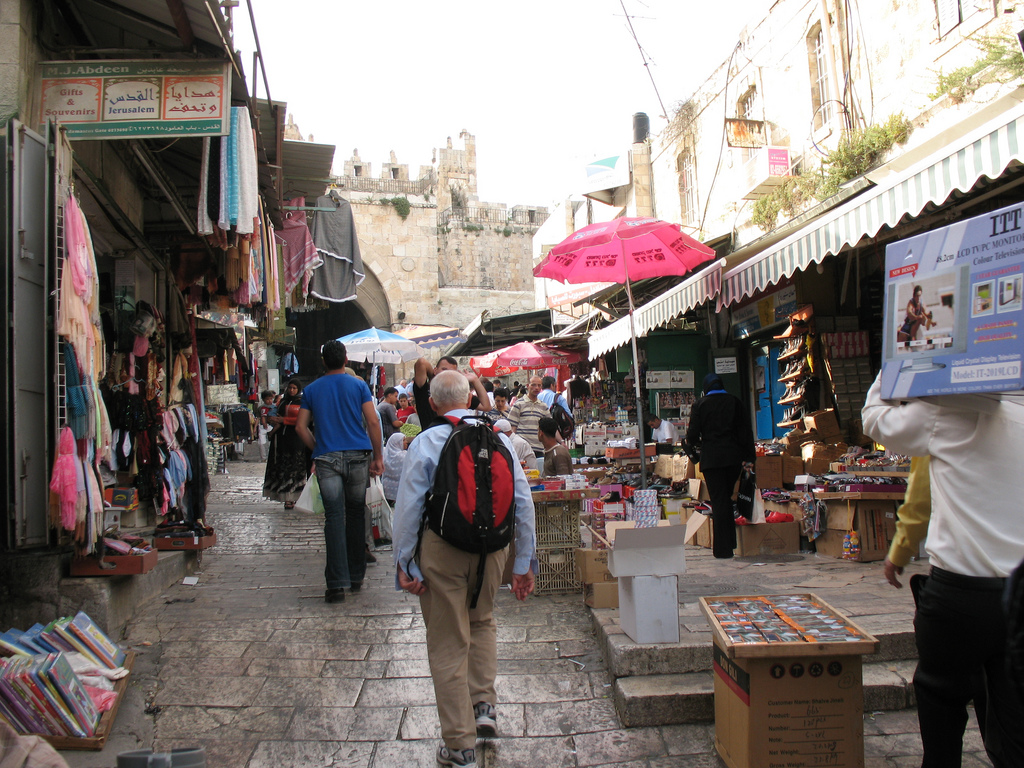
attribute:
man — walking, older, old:
[390, 367, 542, 767]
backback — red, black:
[426, 413, 519, 553]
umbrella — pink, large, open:
[532, 217, 714, 287]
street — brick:
[53, 460, 991, 766]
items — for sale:
[6, 610, 133, 766]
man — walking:
[297, 339, 385, 604]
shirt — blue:
[297, 372, 380, 449]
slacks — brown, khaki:
[414, 528, 507, 751]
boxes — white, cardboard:
[602, 516, 690, 646]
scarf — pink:
[48, 427, 82, 533]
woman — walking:
[262, 381, 313, 511]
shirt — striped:
[507, 393, 553, 453]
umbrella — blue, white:
[321, 324, 429, 364]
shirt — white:
[649, 417, 685, 447]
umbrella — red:
[471, 338, 583, 376]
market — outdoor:
[0, 20, 1023, 756]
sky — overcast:
[180, 0, 762, 209]